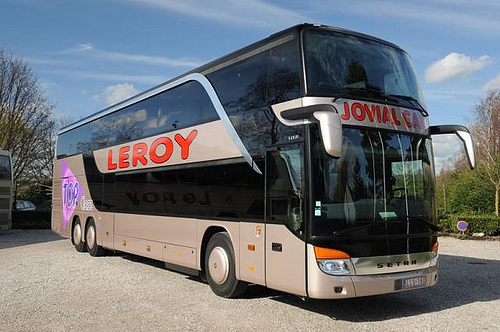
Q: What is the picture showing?
A: A bus.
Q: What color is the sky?
A: Blue.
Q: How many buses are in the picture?
A: One.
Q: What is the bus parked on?
A: Gravel.